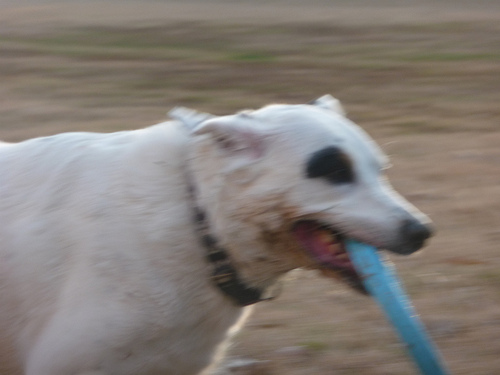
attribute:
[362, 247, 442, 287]
frisbee — blue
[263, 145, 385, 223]
patch — black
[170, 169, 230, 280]
collar — black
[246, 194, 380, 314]
teeth — brown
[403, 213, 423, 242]
nose — black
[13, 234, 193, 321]
dog — white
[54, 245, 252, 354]
dog — white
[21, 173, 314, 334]
dog — white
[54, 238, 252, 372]
dog — white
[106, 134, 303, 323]
dog — white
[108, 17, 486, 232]
background — blurry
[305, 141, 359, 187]
patch — black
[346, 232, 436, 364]
frisbee — blue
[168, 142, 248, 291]
collar — black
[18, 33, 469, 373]
dog — white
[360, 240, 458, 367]
frisbee — blue